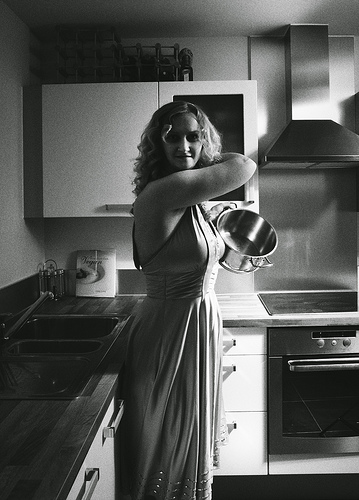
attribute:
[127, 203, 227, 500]
dress — formal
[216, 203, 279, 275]
pot — metal, being held, silver, stainless steel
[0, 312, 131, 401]
sink — metal, steel, empty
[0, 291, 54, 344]
faucet — stainless steel, metal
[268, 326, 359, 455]
oven — silver, stainless steel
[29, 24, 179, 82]
rack — for wine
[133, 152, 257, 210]
arm — in front of neck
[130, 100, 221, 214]
hair — blonde, curly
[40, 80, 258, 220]
cabinets — white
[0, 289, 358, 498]
counter top — made of wood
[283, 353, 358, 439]
window — black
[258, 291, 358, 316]
stove — black, empty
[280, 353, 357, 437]
door — glass, closed